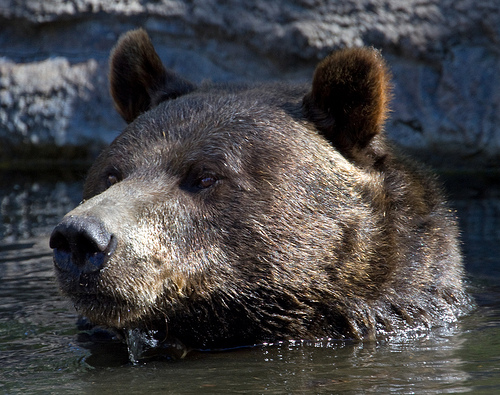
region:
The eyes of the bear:
[103, 168, 218, 189]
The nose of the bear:
[49, 210, 107, 267]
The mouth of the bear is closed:
[69, 285, 132, 305]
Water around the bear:
[0, 187, 497, 394]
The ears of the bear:
[111, 30, 391, 139]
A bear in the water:
[49, 31, 468, 361]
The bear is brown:
[48, 35, 468, 363]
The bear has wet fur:
[48, 30, 466, 363]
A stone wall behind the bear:
[0, 0, 497, 165]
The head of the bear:
[48, 28, 460, 363]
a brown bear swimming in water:
[0, 26, 495, 386]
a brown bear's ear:
[310, 40, 390, 135]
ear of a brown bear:
[110, 25, 185, 120]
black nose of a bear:
[45, 215, 115, 270]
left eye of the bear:
[195, 170, 220, 185]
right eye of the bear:
[100, 165, 115, 185]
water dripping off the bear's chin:
[115, 310, 155, 365]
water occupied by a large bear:
[0, 165, 495, 385]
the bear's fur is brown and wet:
[50, 25, 475, 350]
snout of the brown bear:
[46, 178, 167, 325]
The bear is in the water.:
[2, 16, 498, 393]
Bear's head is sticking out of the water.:
[4, 20, 497, 393]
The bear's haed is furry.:
[32, 15, 494, 367]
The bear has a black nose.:
[38, 18, 482, 391]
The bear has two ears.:
[8, 12, 488, 387]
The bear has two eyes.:
[21, 25, 468, 366]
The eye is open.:
[91, 156, 143, 195]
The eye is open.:
[167, 141, 242, 218]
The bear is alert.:
[41, 15, 490, 387]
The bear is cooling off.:
[11, 15, 499, 389]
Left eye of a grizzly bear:
[177, 151, 232, 199]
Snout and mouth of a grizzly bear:
[42, 191, 181, 330]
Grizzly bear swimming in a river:
[39, 44, 482, 371]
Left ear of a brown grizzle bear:
[298, 44, 394, 158]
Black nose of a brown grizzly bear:
[51, 210, 120, 279]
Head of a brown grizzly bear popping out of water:
[37, 45, 487, 378]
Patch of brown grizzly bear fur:
[288, 175, 441, 289]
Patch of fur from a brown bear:
[258, 169, 411, 276]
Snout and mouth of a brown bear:
[46, 187, 221, 337]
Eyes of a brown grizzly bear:
[94, 148, 226, 197]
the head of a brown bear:
[52, 20, 470, 352]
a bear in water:
[47, 28, 468, 356]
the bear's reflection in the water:
[284, 324, 475, 394]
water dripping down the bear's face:
[72, 277, 186, 367]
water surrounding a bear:
[11, 36, 468, 363]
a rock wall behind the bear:
[1, 0, 490, 163]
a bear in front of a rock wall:
[46, 25, 468, 349]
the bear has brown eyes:
[96, 165, 221, 207]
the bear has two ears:
[108, 28, 385, 135]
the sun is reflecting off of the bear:
[126, 167, 463, 308]